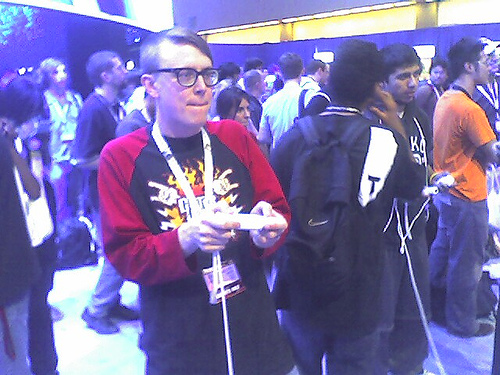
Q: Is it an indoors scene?
A: Yes, it is indoors.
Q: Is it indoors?
A: Yes, it is indoors.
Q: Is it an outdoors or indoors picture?
A: It is indoors.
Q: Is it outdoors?
A: No, it is indoors.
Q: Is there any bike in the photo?
A: No, there are no bikes.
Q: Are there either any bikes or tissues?
A: No, there are no bikes or tissues.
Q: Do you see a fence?
A: No, there are no fences.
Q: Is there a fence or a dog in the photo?
A: No, there are no fences or dogs.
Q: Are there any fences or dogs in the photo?
A: No, there are no fences or dogs.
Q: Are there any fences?
A: No, there are no fences.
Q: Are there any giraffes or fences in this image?
A: No, there are no fences or giraffes.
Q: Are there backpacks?
A: Yes, there is a backpack.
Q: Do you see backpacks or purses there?
A: Yes, there is a backpack.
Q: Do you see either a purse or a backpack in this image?
A: Yes, there is a backpack.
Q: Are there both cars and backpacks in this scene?
A: No, there is a backpack but no cars.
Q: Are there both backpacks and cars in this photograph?
A: No, there is a backpack but no cars.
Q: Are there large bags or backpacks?
A: Yes, there is a large backpack.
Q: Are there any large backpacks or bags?
A: Yes, there is a large backpack.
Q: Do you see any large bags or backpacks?
A: Yes, there is a large backpack.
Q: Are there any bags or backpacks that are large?
A: Yes, the backpack is large.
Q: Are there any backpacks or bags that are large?
A: Yes, the backpack is large.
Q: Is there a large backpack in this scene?
A: Yes, there is a large backpack.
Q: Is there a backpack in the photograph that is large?
A: Yes, there is a backpack that is large.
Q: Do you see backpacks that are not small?
A: Yes, there is a large backpack.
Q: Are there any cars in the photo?
A: No, there are no cars.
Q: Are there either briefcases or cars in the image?
A: No, there are no cars or briefcases.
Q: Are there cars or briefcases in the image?
A: No, there are no cars or briefcases.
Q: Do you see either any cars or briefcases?
A: No, there are no cars or briefcases.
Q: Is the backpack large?
A: Yes, the backpack is large.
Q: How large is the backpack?
A: The backpack is large.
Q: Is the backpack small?
A: No, the backpack is large.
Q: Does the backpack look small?
A: No, the backpack is large.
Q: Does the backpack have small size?
A: No, the backpack is large.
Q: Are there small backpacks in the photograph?
A: No, there is a backpack but it is large.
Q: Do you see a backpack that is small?
A: No, there is a backpack but it is large.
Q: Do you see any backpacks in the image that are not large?
A: No, there is a backpack but it is large.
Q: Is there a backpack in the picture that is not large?
A: No, there is a backpack but it is large.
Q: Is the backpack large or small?
A: The backpack is large.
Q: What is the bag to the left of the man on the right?
A: The bag is a backpack.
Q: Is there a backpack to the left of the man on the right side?
A: Yes, there is a backpack to the left of the man.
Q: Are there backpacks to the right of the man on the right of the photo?
A: No, the backpack is to the left of the man.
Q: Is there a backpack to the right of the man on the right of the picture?
A: No, the backpack is to the left of the man.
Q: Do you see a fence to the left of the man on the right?
A: No, there is a backpack to the left of the man.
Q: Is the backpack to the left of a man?
A: Yes, the backpack is to the left of a man.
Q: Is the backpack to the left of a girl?
A: No, the backpack is to the left of a man.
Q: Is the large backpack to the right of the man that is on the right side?
A: No, the backpack is to the left of the man.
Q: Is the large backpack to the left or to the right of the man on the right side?
A: The backpack is to the left of the man.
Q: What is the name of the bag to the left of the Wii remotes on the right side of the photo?
A: The bag is a backpack.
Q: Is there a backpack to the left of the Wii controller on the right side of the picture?
A: Yes, there is a backpack to the left of the Wii controller.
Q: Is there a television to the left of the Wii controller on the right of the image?
A: No, there is a backpack to the left of the Wii remotes.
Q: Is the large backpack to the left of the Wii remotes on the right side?
A: Yes, the backpack is to the left of the Wii remotes.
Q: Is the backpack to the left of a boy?
A: No, the backpack is to the left of the Wii remotes.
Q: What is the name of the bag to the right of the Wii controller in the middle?
A: The bag is a backpack.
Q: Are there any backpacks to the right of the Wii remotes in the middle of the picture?
A: Yes, there is a backpack to the right of the Wii remotes.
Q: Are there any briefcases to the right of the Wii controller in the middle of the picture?
A: No, there is a backpack to the right of the Wii remotes.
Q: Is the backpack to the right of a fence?
A: No, the backpack is to the right of the Wii controller.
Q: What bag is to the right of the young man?
A: The bag is a backpack.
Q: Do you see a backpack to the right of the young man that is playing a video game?
A: Yes, there is a backpack to the right of the man.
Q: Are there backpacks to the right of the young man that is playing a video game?
A: Yes, there is a backpack to the right of the man.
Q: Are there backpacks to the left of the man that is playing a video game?
A: No, the backpack is to the right of the man.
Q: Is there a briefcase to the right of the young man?
A: No, there is a backpack to the right of the man.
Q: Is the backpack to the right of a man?
A: Yes, the backpack is to the right of a man.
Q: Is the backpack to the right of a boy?
A: No, the backpack is to the right of a man.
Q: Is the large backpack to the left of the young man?
A: No, the backpack is to the right of the man.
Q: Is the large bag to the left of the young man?
A: No, the backpack is to the right of the man.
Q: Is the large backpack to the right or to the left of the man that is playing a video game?
A: The backpack is to the right of the man.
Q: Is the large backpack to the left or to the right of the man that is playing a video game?
A: The backpack is to the right of the man.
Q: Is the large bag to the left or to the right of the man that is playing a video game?
A: The backpack is to the right of the man.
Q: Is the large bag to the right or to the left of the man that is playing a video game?
A: The backpack is to the right of the man.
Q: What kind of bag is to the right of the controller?
A: The bag is a backpack.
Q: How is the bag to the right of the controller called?
A: The bag is a backpack.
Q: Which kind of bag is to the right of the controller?
A: The bag is a backpack.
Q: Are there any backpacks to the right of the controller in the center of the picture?
A: Yes, there is a backpack to the right of the controller.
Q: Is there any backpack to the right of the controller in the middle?
A: Yes, there is a backpack to the right of the controller.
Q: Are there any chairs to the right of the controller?
A: No, there is a backpack to the right of the controller.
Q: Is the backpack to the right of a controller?
A: Yes, the backpack is to the right of a controller.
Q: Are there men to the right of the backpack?
A: Yes, there is a man to the right of the backpack.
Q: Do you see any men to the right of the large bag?
A: Yes, there is a man to the right of the backpack.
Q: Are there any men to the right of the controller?
A: Yes, there is a man to the right of the controller.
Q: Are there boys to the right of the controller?
A: No, there is a man to the right of the controller.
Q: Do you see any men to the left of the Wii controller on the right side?
A: Yes, there is a man to the left of the Wii remotes.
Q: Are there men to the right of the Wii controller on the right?
A: No, the man is to the left of the Wii controller.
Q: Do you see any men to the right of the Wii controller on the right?
A: No, the man is to the left of the Wii controller.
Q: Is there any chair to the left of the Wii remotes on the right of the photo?
A: No, there is a man to the left of the Wii remotes.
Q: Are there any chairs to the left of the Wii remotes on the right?
A: No, there is a man to the left of the Wii remotes.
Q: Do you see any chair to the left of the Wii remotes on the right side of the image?
A: No, there is a man to the left of the Wii remotes.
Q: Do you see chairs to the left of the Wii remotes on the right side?
A: No, there is a man to the left of the Wii remotes.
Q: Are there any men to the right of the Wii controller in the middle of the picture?
A: Yes, there is a man to the right of the Wii remotes.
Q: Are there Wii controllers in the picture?
A: Yes, there is a Wii controller.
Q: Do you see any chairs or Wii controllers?
A: Yes, there is a Wii controller.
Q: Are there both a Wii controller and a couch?
A: No, there is a Wii controller but no couches.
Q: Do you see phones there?
A: No, there are no phones.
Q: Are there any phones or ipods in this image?
A: No, there are no phones or ipods.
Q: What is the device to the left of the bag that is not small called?
A: The device is a Wii controller.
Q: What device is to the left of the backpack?
A: The device is a Wii controller.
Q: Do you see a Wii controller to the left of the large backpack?
A: Yes, there is a Wii controller to the left of the backpack.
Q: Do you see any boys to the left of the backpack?
A: No, there is a Wii controller to the left of the backpack.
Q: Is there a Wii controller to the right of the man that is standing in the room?
A: Yes, there is a Wii controller to the right of the man.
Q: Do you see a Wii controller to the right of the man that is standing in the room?
A: Yes, there is a Wii controller to the right of the man.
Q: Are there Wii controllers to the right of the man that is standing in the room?
A: Yes, there is a Wii controller to the right of the man.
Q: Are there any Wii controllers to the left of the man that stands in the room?
A: No, the Wii controller is to the right of the man.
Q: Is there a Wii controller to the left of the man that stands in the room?
A: No, the Wii controller is to the right of the man.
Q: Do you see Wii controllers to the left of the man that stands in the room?
A: No, the Wii controller is to the right of the man.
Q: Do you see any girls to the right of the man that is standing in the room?
A: No, there is a Wii controller to the right of the man.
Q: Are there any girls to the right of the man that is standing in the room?
A: No, there is a Wii controller to the right of the man.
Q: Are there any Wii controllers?
A: Yes, there is a Wii controller.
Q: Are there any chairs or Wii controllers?
A: Yes, there is a Wii controller.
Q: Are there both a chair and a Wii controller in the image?
A: No, there is a Wii controller but no chairs.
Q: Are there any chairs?
A: No, there are no chairs.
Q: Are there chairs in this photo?
A: No, there are no chairs.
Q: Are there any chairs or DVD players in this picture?
A: No, there are no chairs or DVD players.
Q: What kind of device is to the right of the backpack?
A: The device is a Wii controller.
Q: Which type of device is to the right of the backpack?
A: The device is a Wii controller.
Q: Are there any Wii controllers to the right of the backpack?
A: Yes, there is a Wii controller to the right of the backpack.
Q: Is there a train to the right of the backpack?
A: No, there is a Wii controller to the right of the backpack.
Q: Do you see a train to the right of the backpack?
A: No, there is a Wii controller to the right of the backpack.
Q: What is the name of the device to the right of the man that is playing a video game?
A: The device is a Wii controller.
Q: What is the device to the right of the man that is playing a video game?
A: The device is a Wii controller.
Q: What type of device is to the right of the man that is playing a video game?
A: The device is a Wii controller.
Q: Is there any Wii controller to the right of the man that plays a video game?
A: Yes, there is a Wii controller to the right of the man.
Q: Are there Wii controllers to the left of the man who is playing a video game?
A: No, the Wii controller is to the right of the man.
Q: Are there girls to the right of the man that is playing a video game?
A: No, there is a Wii controller to the right of the man.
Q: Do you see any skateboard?
A: No, there are no skateboards.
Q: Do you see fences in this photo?
A: No, there are no fences.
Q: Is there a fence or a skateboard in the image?
A: No, there are no fences or skateboards.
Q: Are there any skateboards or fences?
A: No, there are no fences or skateboards.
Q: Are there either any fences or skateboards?
A: No, there are no fences or skateboards.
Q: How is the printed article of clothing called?
A: The clothing item is a t-shirt.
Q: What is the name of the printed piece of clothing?
A: The clothing item is a t-shirt.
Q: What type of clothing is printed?
A: The clothing is a t-shirt.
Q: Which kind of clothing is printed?
A: The clothing is a t-shirt.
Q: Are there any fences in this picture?
A: No, there are no fences.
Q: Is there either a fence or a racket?
A: No, there are no fences or rackets.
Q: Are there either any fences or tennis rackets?
A: No, there are no fences or tennis rackets.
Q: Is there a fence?
A: No, there are no fences.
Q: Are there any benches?
A: No, there are no benches.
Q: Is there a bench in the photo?
A: No, there are no benches.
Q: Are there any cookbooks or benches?
A: No, there are no benches or cookbooks.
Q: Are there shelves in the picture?
A: No, there are no shelves.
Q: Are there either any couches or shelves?
A: No, there are no shelves or couches.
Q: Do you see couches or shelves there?
A: No, there are no shelves or couches.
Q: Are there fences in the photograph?
A: No, there are no fences.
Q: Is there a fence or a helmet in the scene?
A: No, there are no fences or helmets.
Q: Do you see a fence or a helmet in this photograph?
A: No, there are no fences or helmets.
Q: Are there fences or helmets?
A: No, there are no fences or helmets.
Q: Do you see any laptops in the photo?
A: No, there are no laptops.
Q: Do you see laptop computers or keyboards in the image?
A: No, there are no laptop computers or keyboards.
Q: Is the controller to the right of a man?
A: No, the controller is to the left of a man.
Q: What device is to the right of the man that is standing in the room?
A: The device is a controller.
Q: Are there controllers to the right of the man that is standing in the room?
A: Yes, there is a controller to the right of the man.